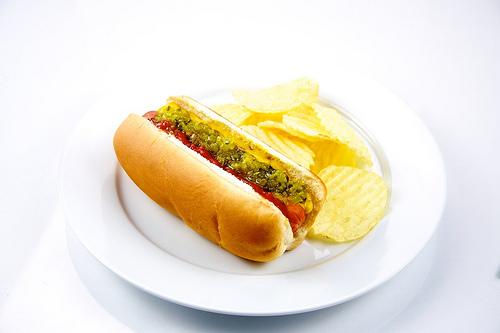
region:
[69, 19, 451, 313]
this is a plate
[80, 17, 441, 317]
food on a plate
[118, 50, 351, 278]
this is a hotdog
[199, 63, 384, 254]
a side of chips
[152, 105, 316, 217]
relish on the hot dog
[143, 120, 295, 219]
ketchup on the hot dog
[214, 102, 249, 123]
potato chip on white round plate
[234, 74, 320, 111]
potato chip on white round plate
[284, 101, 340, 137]
potato chip on white round plate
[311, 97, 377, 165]
potato chip on white round plate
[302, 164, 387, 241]
potato chip on white round plate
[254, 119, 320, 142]
potato chip on white round plate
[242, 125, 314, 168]
potato chip on white round plate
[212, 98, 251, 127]
potato chip next to hot dog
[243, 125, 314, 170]
potato chip next to hot dog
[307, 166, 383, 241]
potato chip next to hot dog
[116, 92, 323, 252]
hotdog in bun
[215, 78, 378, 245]
potato chips on the plate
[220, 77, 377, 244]
ruffle ridge potato chips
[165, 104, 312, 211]
green relish on the hotdog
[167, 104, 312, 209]
mustard on the hotdog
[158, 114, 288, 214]
ketchup on the hotdog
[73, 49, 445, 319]
white plate the food is on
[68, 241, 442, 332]
shadow of the plate on the table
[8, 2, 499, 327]
white table the plate is on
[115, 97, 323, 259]
bun the hotdog is in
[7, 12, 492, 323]
white plate on white surface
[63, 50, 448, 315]
round plate holding a quick meal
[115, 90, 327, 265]
brown hot dog inside of brown bun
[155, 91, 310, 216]
wide line of green pickle relish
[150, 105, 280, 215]
thin line of ketchup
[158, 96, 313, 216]
thick line of mustard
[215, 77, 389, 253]
side of ruffled potato chips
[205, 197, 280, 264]
lines across hot dog bun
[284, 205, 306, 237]
lines along end of hot dog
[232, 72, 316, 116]
upward curve of potato chip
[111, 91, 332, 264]
hot dog sandwich on white plate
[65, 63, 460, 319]
round white ceramic plate with lip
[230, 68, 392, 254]
side of ridged potato chips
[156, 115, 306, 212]
green pickle relish on hot dog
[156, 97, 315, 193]
mustard on hot dog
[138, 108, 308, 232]
brown hot dog inside white bun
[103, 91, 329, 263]
golden white hot dog bun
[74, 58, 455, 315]
hot dog with potato chips on white plate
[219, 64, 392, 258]
round crisp yellow potato chips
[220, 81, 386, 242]
THE CHIPS ARE YELLOW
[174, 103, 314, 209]
THE MUSTARD IS YELLOW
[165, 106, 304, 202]
the relish is green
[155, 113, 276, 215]
the ketchup is red